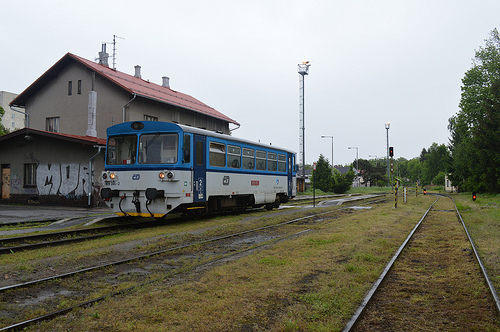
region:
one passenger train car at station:
[56, 47, 313, 224]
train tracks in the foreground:
[63, 217, 480, 303]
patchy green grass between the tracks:
[153, 257, 364, 317]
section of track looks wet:
[35, 239, 307, 299]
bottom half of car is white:
[112, 175, 298, 210]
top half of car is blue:
[111, 116, 298, 171]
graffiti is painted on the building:
[3, 155, 96, 210]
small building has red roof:
[23, 42, 241, 127]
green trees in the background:
[302, 145, 495, 201]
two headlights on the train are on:
[91, 162, 189, 189]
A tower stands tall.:
[288, 59, 309, 176]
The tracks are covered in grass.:
[282, 216, 319, 237]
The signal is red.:
[469, 189, 477, 200]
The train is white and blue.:
[108, 123, 294, 221]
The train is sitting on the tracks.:
[101, 123, 301, 228]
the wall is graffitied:
[36, 162, 93, 198]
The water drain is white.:
[9, 106, 31, 127]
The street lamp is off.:
[346, 141, 362, 187]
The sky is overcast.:
[329, 24, 419, 98]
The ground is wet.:
[75, 230, 295, 305]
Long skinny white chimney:
[81, 87, 102, 137]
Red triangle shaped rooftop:
[6, 50, 246, 125]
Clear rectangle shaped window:
[135, 130, 175, 165]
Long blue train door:
[190, 130, 205, 201]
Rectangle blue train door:
[190, 130, 205, 205]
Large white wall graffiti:
[35, 156, 91, 191]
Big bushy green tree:
[445, 20, 495, 190]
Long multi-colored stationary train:
[95, 115, 300, 215]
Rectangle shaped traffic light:
[420, 185, 425, 195]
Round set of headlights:
[100, 170, 172, 180]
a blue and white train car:
[82, 104, 309, 228]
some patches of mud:
[112, 244, 212, 289]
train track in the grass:
[316, 239, 426, 330]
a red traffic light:
[411, 175, 433, 202]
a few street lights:
[311, 130, 371, 192]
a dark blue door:
[181, 129, 218, 211]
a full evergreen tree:
[305, 148, 343, 200]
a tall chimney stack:
[78, 71, 103, 145]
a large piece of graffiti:
[20, 157, 104, 212]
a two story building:
[6, 70, 282, 235]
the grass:
[134, 218, 334, 325]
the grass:
[185, 212, 302, 310]